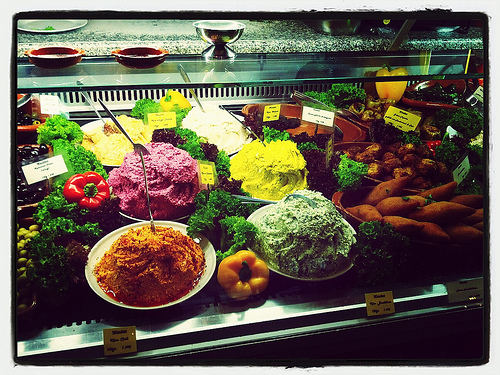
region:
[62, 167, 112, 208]
red bell pepper in case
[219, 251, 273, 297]
yellow bell pepper in case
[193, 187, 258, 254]
kale as a garnish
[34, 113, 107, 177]
green garnish in case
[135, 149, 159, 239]
serving utensil in food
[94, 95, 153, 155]
serving utensil in food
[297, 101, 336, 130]
white with black lettering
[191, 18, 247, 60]
silver measuring bowl on top of case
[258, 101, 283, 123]
yellow sign with black writing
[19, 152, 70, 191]
white sign with black lettering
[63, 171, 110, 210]
red bell pepper in salad bar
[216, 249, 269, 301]
a yellow bell pepper in salad bar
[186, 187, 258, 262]
green parsley on salad bar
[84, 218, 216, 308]
orange gelatin salad on salad bar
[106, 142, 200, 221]
pink gelatin salad on the salad bar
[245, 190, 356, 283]
green gelatin salad on the salad bar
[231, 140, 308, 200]
yellow gelatin salad on the salad bar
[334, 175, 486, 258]
sweet potatoes in a brown bowl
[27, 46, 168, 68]
two brown bowls on top of salad bar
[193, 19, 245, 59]
silver bowl on top of salad bar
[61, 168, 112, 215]
A large red pepper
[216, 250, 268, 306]
A large yellow pepper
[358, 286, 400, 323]
Price tag on a produce shelf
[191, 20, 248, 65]
A metal goblet sitting on a shelf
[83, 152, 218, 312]
A orange dessert with a fork in it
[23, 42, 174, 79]
Two dishes laying on a shelf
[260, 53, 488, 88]
A glass shelf above produce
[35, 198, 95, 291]
Decorative green leaving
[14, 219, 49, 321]
A bunch of green olives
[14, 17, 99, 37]
An empty plate sitting on a shelf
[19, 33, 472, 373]
food on display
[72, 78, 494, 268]
food for sale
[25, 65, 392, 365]
food that is on display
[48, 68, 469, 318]
bowls container food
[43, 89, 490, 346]
food in large bowls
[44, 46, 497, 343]
spoons in the food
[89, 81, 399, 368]
food with spoons in them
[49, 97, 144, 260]
red pepper next to food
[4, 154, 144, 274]
red pepper on display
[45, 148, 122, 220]
bell pepper is red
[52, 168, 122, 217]
bell pepper has green stem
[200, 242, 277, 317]
bell pepper is yellow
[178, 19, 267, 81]
silver bowl on counter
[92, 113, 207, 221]
food is light pink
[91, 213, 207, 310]
food item is orange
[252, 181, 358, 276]
food item is light green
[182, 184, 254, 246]
parsley is dark green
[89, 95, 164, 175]
spoon is stuck in food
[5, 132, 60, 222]
black olives on display